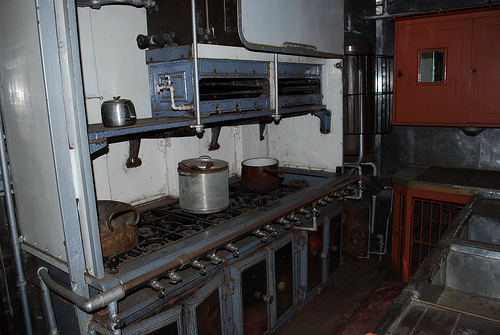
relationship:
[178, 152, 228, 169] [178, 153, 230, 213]
lid on pot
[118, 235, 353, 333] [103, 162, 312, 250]
cabinets below stove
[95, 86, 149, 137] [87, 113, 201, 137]
kettle on shelf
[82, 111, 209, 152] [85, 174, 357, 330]
shelf above stove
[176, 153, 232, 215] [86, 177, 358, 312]
pot on stove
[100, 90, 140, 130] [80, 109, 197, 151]
pot on shelf